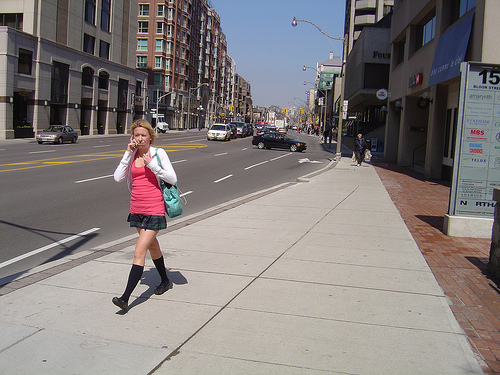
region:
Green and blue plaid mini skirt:
[126, 212, 168, 230]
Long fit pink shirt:
[128, 150, 167, 215]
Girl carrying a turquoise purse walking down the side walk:
[110, 120, 183, 306]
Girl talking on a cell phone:
[118, 118, 156, 155]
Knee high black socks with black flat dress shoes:
[107, 256, 174, 311]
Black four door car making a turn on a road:
[250, 130, 307, 152]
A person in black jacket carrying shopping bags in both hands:
[351, 133, 371, 165]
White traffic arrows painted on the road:
[296, 155, 325, 165]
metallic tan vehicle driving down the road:
[36, 123, 78, 143]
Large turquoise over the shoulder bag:
[153, 145, 183, 217]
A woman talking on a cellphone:
[102, 118, 190, 317]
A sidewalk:
[1, 133, 498, 373]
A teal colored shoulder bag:
[142, 148, 185, 220]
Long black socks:
[115, 253, 173, 300]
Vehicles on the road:
[34, 99, 324, 189]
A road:
[0, 97, 337, 347]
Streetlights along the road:
[288, 18, 351, 133]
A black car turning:
[250, 127, 309, 154]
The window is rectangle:
[135, 0, 155, 21]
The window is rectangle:
[134, 18, 154, 41]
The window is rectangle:
[133, 33, 153, 54]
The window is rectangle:
[133, 53, 150, 70]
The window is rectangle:
[156, 0, 166, 24]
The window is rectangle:
[153, 13, 168, 38]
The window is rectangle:
[148, 35, 164, 54]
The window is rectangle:
[152, 49, 162, 74]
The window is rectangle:
[179, 12, 188, 30]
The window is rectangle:
[177, 45, 188, 63]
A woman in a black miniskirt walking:
[108, 113, 188, 313]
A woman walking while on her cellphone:
[113, 114, 184, 315]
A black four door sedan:
[250, 127, 308, 155]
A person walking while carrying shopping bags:
[350, 131, 375, 168]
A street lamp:
[286, 12, 351, 166]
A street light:
[287, 12, 351, 167]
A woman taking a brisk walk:
[108, 114, 183, 316]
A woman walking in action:
[112, 106, 184, 312]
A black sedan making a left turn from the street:
[211, 124, 326, 176]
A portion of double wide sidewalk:
[222, 181, 427, 337]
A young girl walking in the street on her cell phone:
[103, 112, 189, 318]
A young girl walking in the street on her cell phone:
[97, 116, 187, 318]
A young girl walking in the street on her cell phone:
[105, 113, 186, 314]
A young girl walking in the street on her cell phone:
[105, 112, 190, 313]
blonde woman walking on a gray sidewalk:
[112, 117, 184, 312]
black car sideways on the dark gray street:
[249, 128, 309, 156]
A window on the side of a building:
[137, 20, 149, 34]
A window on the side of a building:
[138, 39, 148, 50]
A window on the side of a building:
[137, 55, 146, 66]